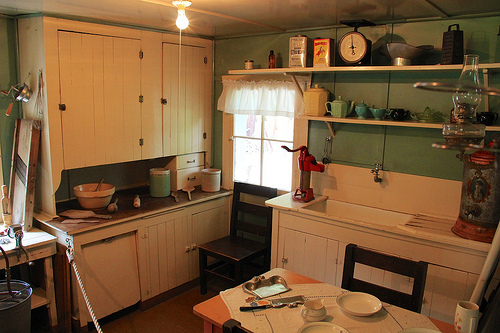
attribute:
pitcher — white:
[295, 294, 334, 326]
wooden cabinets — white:
[36, 18, 258, 160]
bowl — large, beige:
[76, 179, 117, 209]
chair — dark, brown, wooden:
[197, 179, 279, 283]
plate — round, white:
[333, 285, 387, 324]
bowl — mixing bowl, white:
[72, 177, 117, 207]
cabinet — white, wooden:
[16, 14, 213, 171]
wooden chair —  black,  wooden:
[191, 177, 271, 302]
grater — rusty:
[438, 21, 467, 72]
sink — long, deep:
[303, 197, 415, 225]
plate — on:
[335, 290, 382, 316]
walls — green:
[322, 63, 492, 165]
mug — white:
[446, 290, 484, 331]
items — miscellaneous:
[285, 33, 392, 72]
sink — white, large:
[256, 155, 494, 328]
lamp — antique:
[434, 43, 497, 160]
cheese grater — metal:
[440, 21, 465, 63]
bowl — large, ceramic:
[47, 160, 151, 217]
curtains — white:
[209, 81, 307, 198]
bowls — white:
[287, 278, 393, 330]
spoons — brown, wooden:
[171, 185, 195, 205]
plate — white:
[331, 287, 386, 322]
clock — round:
[332, 25, 370, 67]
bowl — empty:
[328, 282, 392, 318]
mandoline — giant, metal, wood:
[3, 111, 67, 246]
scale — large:
[326, 21, 375, 71]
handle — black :
[238, 302, 268, 311]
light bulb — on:
[174, 7, 191, 29]